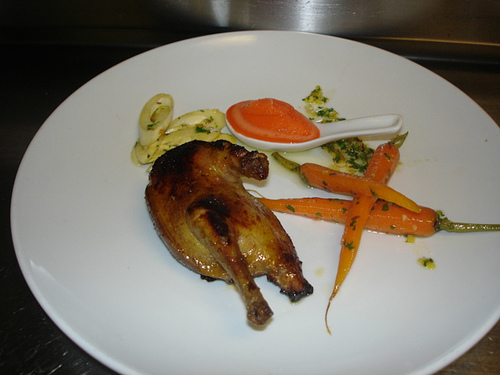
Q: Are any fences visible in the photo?
A: No, there are no fences.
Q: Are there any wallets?
A: No, there are no wallets.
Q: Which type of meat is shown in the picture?
A: The meat is chicken.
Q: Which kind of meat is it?
A: The meat is chicken.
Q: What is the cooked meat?
A: The meat is chicken.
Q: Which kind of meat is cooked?
A: The meat is chicken.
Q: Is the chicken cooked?
A: Yes, the chicken is cooked.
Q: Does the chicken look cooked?
A: Yes, the chicken is cooked.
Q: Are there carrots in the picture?
A: Yes, there is a carrot.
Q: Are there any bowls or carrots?
A: Yes, there is a carrot.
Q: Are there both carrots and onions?
A: No, there is a carrot but no onions.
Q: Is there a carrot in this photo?
A: Yes, there is a carrot.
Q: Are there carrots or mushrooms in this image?
A: Yes, there is a carrot.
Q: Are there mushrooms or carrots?
A: Yes, there is a carrot.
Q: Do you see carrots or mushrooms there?
A: Yes, there is a carrot.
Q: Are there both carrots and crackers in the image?
A: No, there is a carrot but no crackers.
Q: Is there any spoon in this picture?
A: Yes, there is a spoon.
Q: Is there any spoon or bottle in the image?
A: Yes, there is a spoon.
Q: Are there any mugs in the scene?
A: No, there are no mugs.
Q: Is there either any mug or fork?
A: No, there are no mugs or forks.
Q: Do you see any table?
A: Yes, there is a table.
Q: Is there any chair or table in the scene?
A: Yes, there is a table.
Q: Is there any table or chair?
A: Yes, there is a table.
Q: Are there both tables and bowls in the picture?
A: No, there is a table but no bowls.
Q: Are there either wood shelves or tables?
A: Yes, there is a wood table.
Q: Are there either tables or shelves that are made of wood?
A: Yes, the table is made of wood.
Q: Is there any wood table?
A: Yes, there is a table that is made of wood.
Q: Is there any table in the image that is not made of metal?
A: Yes, there is a table that is made of wood.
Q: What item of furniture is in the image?
A: The piece of furniture is a table.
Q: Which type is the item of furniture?
A: The piece of furniture is a table.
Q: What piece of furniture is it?
A: The piece of furniture is a table.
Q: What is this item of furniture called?
A: This is a table.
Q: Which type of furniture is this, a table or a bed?
A: This is a table.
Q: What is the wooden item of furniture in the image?
A: The piece of furniture is a table.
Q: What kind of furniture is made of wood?
A: The furniture is a table.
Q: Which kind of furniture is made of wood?
A: The furniture is a table.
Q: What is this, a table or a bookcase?
A: This is a table.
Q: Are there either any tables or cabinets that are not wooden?
A: No, there is a table but it is wooden.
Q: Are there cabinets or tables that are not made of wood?
A: No, there is a table but it is made of wood.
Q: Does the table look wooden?
A: Yes, the table is wooden.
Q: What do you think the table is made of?
A: The table is made of wood.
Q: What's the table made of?
A: The table is made of wood.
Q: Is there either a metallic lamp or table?
A: No, there is a table but it is wooden.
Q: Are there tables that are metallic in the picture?
A: No, there is a table but it is wooden.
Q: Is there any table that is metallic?
A: No, there is a table but it is wooden.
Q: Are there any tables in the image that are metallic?
A: No, there is a table but it is wooden.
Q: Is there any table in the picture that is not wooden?
A: No, there is a table but it is wooden.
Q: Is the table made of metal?
A: No, the table is made of wood.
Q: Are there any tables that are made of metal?
A: No, there is a table but it is made of wood.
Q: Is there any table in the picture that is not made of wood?
A: No, there is a table but it is made of wood.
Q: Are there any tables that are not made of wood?
A: No, there is a table but it is made of wood.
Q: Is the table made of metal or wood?
A: The table is made of wood.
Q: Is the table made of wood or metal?
A: The table is made of wood.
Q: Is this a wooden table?
A: Yes, this is a wooden table.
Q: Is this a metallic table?
A: No, this is a wooden table.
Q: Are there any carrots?
A: Yes, there are carrots.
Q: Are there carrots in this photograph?
A: Yes, there are carrots.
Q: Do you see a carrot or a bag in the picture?
A: Yes, there are carrots.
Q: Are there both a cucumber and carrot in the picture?
A: No, there are carrots but no cucumbers.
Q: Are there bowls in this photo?
A: No, there are no bowls.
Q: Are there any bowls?
A: No, there are no bowls.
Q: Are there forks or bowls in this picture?
A: No, there are no bowls or forks.